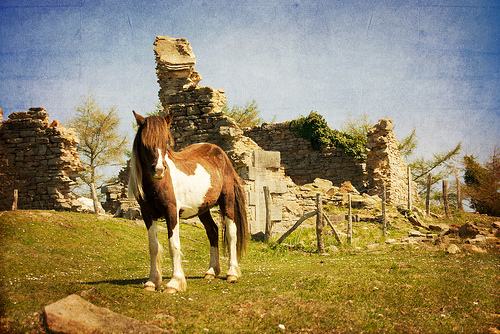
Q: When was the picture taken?
A: Daytime.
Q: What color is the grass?
A: Green.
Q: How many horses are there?
A: One.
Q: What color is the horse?
A: Brown and white.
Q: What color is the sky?
A: Blue.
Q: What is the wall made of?
A: Stone.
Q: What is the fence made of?
A: Wood and wire.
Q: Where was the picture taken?
A: In a field.